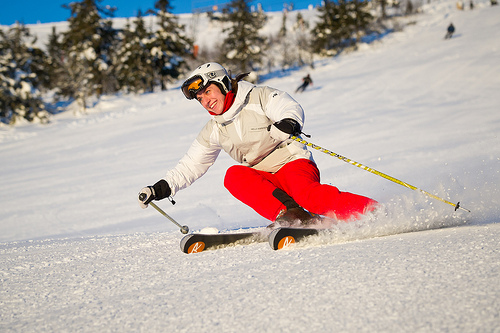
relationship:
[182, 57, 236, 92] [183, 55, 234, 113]
helmet on head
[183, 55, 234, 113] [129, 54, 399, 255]
head of skier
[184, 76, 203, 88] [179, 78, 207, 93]
glass of goggles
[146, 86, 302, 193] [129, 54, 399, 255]
coat on skier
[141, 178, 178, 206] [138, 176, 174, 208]
glove on hand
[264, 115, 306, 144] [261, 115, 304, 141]
glove on hand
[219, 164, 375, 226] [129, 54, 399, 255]
pants on skier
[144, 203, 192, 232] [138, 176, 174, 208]
pole in hand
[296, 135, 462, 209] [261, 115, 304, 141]
pole in hand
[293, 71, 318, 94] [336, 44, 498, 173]
people on hill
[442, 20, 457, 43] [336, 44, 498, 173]
skier on hill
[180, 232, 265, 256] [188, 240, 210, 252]
ski with emblem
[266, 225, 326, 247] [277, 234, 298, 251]
ski with emblem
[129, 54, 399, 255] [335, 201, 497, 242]
skier kicked snow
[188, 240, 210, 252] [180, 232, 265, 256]
emblem on ski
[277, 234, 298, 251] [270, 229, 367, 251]
emblem on bottom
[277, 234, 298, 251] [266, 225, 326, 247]
emblem on ski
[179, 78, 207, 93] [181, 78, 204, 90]
goggles with glass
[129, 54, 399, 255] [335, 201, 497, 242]
skier in snow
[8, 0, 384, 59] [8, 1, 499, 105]
trees in background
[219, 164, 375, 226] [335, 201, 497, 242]
pants for snow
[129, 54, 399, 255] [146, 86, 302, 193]
woman in coat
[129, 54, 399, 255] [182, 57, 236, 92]
woman in helmet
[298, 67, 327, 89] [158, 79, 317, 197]
people going coat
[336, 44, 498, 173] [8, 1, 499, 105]
hill in background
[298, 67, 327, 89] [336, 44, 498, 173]
people on hill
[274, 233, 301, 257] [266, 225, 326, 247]
emblem on ski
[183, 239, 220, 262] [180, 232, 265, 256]
emblem on ski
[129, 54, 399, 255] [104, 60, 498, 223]
skier enjoying skiing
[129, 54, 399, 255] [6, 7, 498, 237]
skier enjoying day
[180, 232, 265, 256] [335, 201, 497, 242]
ski in snow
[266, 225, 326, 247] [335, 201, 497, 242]
ski in snow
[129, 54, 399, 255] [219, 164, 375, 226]
skier wearing pants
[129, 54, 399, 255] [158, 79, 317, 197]
skier wearing coat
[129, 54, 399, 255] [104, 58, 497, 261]
skier on skiing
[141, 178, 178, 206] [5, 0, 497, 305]
glove in air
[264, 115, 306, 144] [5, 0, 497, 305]
glove in air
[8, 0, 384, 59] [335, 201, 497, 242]
trees in snow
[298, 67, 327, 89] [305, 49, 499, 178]
people on slope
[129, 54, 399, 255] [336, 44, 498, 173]
skier on hill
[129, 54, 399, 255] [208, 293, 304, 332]
skier near camera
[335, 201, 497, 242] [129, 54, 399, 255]
snow behind skier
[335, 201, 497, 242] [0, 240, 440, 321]
snow on ground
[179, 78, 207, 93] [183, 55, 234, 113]
goggles on head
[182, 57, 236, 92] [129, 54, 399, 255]
helmet on skier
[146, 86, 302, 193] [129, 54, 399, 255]
coat of skier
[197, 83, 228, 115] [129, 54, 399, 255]
face of skier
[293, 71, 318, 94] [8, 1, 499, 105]
people in background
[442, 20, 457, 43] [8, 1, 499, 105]
skier in background